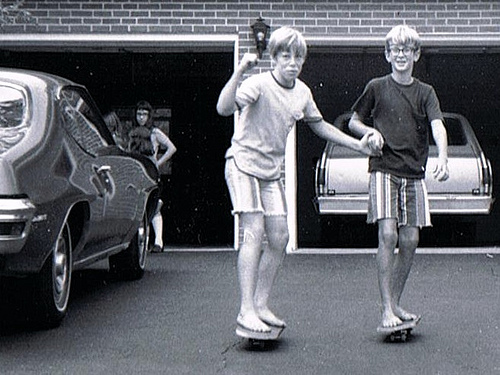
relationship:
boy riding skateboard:
[211, 25, 376, 334] [232, 314, 284, 346]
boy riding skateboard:
[345, 21, 446, 329] [375, 312, 422, 340]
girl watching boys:
[127, 100, 174, 252] [220, 20, 334, 330]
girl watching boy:
[127, 100, 174, 252] [348, 25, 449, 327]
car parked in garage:
[312, 90, 498, 238] [1, 30, 484, 249]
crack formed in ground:
[218, 338, 240, 370] [8, 242, 496, 367]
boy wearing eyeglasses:
[345, 21, 446, 329] [378, 41, 417, 54]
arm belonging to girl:
[155, 130, 177, 165] [124, 100, 177, 253]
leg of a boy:
[375, 218, 420, 308] [345, 21, 446, 329]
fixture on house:
[246, 15, 268, 58] [1, 2, 498, 256]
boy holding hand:
[345, 21, 446, 329] [428, 154, 455, 188]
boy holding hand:
[211, 25, 376, 334] [367, 127, 388, 148]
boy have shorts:
[348, 25, 449, 327] [365, 170, 434, 230]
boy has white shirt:
[211, 25, 376, 334] [229, 71, 321, 178]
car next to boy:
[1, 66, 163, 324] [211, 25, 376, 334]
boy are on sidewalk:
[216, 27, 383, 332] [60, 253, 497, 374]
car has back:
[312, 112, 494, 242] [312, 158, 493, 221]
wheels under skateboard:
[387, 332, 408, 342] [373, 294, 422, 339]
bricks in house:
[93, 13, 156, 33] [1, 2, 498, 256]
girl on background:
[124, 100, 177, 253] [70, 91, 228, 160]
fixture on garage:
[249, 17, 270, 60] [292, 34, 488, 254]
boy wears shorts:
[216, 27, 383, 332] [221, 154, 293, 217]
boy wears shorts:
[348, 25, 449, 327] [361, 169, 431, 232]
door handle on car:
[75, 112, 177, 242] [1, 66, 163, 324]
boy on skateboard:
[216, 27, 383, 332] [228, 317, 284, 351]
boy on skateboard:
[348, 25, 449, 327] [372, 317, 422, 344]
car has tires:
[0, 67, 161, 328] [2, 61, 162, 328]